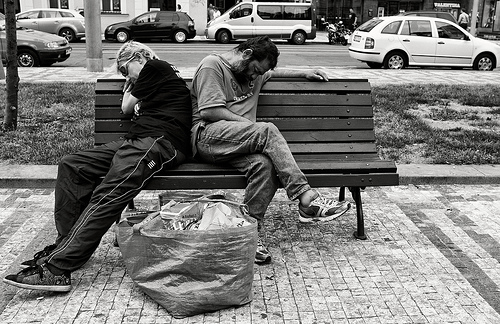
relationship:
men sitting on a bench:
[35, 53, 390, 307] [90, 64, 404, 216]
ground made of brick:
[0, 163, 499, 323] [334, 258, 354, 277]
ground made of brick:
[0, 163, 499, 323] [324, 261, 341, 281]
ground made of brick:
[0, 163, 499, 323] [371, 283, 389, 305]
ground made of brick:
[0, 163, 499, 323] [294, 277, 315, 301]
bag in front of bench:
[115, 190, 260, 320] [89, 77, 399, 242]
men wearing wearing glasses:
[3, 40, 192, 292] [115, 54, 138, 76]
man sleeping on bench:
[200, 36, 358, 267] [89, 77, 399, 242]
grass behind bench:
[391, 83, 496, 154] [89, 77, 399, 242]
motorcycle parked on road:
[322, 10, 357, 42] [57, 26, 382, 71]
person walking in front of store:
[456, 7, 473, 31] [366, 4, 475, 39]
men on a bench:
[3, 40, 192, 292] [84, 70, 425, 218]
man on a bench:
[191, 36, 352, 264] [84, 70, 425, 218]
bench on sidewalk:
[93, 77, 402, 182] [20, 197, 435, 292]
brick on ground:
[430, 226, 457, 252] [0, 163, 499, 323]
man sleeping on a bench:
[191, 36, 352, 264] [89, 77, 399, 242]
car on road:
[347, 16, 498, 71] [44, 31, 371, 66]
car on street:
[204, 2, 317, 45] [31, 31, 346, 77]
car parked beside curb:
[347, 16, 498, 71] [279, 60, 497, 78]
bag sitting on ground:
[115, 198, 258, 320] [1, 166, 498, 322]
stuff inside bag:
[143, 190, 255, 231] [115, 190, 260, 320]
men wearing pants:
[3, 40, 192, 292] [41, 118, 211, 286]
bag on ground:
[115, 190, 260, 320] [1, 166, 498, 322]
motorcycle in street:
[321, 18, 352, 47] [309, 24, 381, 67]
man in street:
[191, 36, 352, 264] [11, 34, 499, 73]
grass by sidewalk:
[0, 80, 500, 167] [35, 167, 482, 307]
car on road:
[348, 16, 499, 71] [44, 25, 471, 70]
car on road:
[203, 0, 318, 43] [48, 39, 373, 69]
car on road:
[0, 3, 89, 40] [79, 44, 404, 80]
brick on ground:
[314, 305, 332, 320] [0, 163, 499, 323]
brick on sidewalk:
[370, 292, 389, 317] [1, 153, 486, 320]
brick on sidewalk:
[334, 243, 496, 305] [1, 153, 486, 320]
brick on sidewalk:
[427, 295, 452, 315] [24, 149, 485, 312]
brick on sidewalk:
[96, 285, 117, 301] [24, 149, 485, 312]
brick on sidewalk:
[351, 293, 376, 316] [24, 149, 485, 312]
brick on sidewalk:
[311, 265, 328, 278] [24, 149, 485, 312]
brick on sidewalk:
[282, 308, 300, 320] [24, 149, 485, 312]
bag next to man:
[115, 190, 260, 320] [190, 29, 361, 276]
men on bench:
[3, 40, 192, 292] [39, 29, 419, 252]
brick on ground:
[384, 297, 407, 316] [4, 67, 499, 322]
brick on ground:
[276, 295, 298, 313] [4, 67, 499, 322]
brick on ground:
[394, 238, 414, 251] [4, 67, 499, 322]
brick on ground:
[95, 287, 117, 305] [4, 67, 499, 322]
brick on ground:
[441, 227, 458, 242] [4, 67, 499, 322]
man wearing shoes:
[191, 36, 352, 264] [237, 185, 352, 277]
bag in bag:
[115, 198, 258, 320] [158, 199, 288, 308]